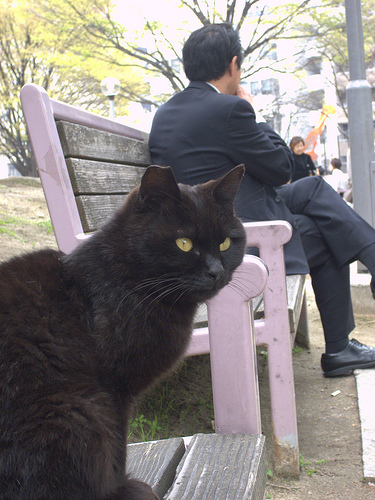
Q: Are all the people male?
A: No, they are both male and female.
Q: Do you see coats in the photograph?
A: Yes, there is a coat.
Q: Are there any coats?
A: Yes, there is a coat.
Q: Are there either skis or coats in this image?
A: Yes, there is a coat.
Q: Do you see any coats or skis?
A: Yes, there is a coat.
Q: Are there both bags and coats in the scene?
A: No, there is a coat but no bags.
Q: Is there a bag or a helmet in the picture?
A: No, there are no bags or helmets.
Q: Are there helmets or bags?
A: No, there are no bags or helmets.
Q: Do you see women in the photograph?
A: Yes, there is a woman.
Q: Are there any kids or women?
A: Yes, there is a woman.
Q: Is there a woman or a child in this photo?
A: Yes, there is a woman.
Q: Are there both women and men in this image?
A: Yes, there are both a woman and a man.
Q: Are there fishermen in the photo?
A: No, there are no fishermen.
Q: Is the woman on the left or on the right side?
A: The woman is on the right of the image.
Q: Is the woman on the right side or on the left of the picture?
A: The woman is on the right of the image.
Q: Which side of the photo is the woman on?
A: The woman is on the right of the image.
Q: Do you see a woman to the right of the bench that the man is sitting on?
A: Yes, there is a woman to the right of the bench.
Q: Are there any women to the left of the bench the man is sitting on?
A: No, the woman is to the right of the bench.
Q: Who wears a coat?
A: The woman wears a coat.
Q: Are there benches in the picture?
A: Yes, there is a bench.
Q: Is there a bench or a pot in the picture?
A: Yes, there is a bench.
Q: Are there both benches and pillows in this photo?
A: No, there is a bench but no pillows.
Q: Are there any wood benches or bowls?
A: Yes, there is a wood bench.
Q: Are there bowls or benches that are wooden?
A: Yes, the bench is wooden.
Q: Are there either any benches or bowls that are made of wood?
A: Yes, the bench is made of wood.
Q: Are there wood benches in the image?
A: Yes, there is a wood bench.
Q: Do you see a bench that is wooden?
A: Yes, there is a bench that is wooden.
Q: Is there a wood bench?
A: Yes, there is a bench that is made of wood.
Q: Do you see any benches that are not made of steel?
A: Yes, there is a bench that is made of wood.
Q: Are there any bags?
A: No, there are no bags.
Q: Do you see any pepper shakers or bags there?
A: No, there are no bags or pepper shakers.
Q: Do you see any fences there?
A: No, there are no fences.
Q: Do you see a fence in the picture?
A: No, there are no fences.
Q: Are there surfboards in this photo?
A: No, there are no surfboards.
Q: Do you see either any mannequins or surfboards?
A: No, there are no surfboards or mannequins.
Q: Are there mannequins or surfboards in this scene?
A: No, there are no surfboards or mannequins.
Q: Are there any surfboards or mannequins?
A: No, there are no surfboards or mannequins.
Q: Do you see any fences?
A: No, there are no fences.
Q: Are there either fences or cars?
A: No, there are no fences or cars.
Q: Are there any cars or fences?
A: No, there are no fences or cars.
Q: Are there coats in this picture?
A: Yes, there is a coat.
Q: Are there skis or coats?
A: Yes, there is a coat.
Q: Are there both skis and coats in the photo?
A: No, there is a coat but no skis.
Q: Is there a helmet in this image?
A: No, there are no helmets.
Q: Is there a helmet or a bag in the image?
A: No, there are no helmets or bags.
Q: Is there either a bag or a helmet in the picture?
A: No, there are no helmets or bags.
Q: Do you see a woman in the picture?
A: Yes, there is a woman.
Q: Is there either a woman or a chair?
A: Yes, there is a woman.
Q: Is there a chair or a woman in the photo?
A: Yes, there is a woman.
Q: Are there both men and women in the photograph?
A: Yes, there are both a woman and a man.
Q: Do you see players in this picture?
A: No, there are no players.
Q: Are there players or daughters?
A: No, there are no players or daughters.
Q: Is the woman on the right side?
A: Yes, the woman is on the right of the image.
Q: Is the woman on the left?
A: No, the woman is on the right of the image.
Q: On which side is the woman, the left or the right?
A: The woman is on the right of the image.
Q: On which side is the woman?
A: The woman is on the right of the image.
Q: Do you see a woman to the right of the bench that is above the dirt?
A: Yes, there is a woman to the right of the bench.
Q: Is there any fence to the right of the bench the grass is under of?
A: No, there is a woman to the right of the bench.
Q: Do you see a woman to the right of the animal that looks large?
A: Yes, there is a woman to the right of the cat.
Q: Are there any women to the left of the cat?
A: No, the woman is to the right of the cat.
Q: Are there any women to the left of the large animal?
A: No, the woman is to the right of the cat.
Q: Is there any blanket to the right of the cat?
A: No, there is a woman to the right of the cat.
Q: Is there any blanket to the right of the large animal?
A: No, there is a woman to the right of the cat.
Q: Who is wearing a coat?
A: The woman is wearing a coat.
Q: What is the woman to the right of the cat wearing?
A: The woman is wearing a coat.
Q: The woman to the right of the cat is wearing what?
A: The woman is wearing a coat.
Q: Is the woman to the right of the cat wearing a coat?
A: Yes, the woman is wearing a coat.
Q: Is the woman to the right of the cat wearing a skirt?
A: No, the woman is wearing a coat.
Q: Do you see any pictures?
A: No, there are no pictures.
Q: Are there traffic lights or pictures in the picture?
A: No, there are no pictures or traffic lights.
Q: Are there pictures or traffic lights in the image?
A: No, there are no pictures or traffic lights.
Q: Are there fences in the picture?
A: No, there are no fences.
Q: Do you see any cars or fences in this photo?
A: No, there are no fences or cars.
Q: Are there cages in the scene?
A: No, there are no cages.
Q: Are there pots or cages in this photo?
A: No, there are no cages or pots.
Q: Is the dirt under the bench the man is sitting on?
A: Yes, the dirt is under the bench.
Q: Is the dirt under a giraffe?
A: No, the dirt is under the bench.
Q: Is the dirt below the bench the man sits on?
A: Yes, the dirt is below the bench.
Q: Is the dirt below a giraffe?
A: No, the dirt is below the bench.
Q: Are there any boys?
A: No, there are no boys.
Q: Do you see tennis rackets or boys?
A: No, there are no boys or tennis rackets.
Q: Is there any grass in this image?
A: Yes, there is grass.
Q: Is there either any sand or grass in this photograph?
A: Yes, there is grass.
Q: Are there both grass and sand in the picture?
A: No, there is grass but no sand.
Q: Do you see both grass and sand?
A: No, there is grass but no sand.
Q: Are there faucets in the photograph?
A: No, there are no faucets.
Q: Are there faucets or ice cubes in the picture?
A: No, there are no faucets or ice cubes.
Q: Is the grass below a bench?
A: Yes, the grass is below a bench.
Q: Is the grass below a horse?
A: No, the grass is below a bench.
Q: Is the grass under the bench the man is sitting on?
A: Yes, the grass is under the bench.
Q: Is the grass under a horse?
A: No, the grass is under the bench.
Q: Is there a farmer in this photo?
A: No, there are no farmers.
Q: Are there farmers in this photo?
A: No, there are no farmers.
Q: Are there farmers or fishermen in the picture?
A: No, there are no farmers or fishermen.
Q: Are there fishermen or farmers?
A: No, there are no farmers or fishermen.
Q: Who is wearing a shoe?
A: The man is wearing a shoe.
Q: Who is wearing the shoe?
A: The man is wearing a shoe.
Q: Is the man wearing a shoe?
A: Yes, the man is wearing a shoe.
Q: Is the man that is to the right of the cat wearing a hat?
A: No, the man is wearing a shoe.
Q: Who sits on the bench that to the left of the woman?
A: The man sits on the bench.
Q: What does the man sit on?
A: The man sits on the bench.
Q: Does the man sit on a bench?
A: Yes, the man sits on a bench.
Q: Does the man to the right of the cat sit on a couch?
A: No, the man sits on a bench.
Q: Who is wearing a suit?
A: The man is wearing a suit.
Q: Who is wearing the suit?
A: The man is wearing a suit.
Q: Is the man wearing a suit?
A: Yes, the man is wearing a suit.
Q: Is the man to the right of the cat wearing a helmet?
A: No, the man is wearing a suit.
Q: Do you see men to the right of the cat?
A: Yes, there is a man to the right of the cat.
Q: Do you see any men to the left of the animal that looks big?
A: No, the man is to the right of the cat.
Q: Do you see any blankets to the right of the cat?
A: No, there is a man to the right of the cat.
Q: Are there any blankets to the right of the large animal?
A: No, there is a man to the right of the cat.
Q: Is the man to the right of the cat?
A: Yes, the man is to the right of the cat.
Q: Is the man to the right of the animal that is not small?
A: Yes, the man is to the right of the cat.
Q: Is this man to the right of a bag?
A: No, the man is to the right of the cat.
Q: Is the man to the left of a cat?
A: No, the man is to the right of a cat.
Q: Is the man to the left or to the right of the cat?
A: The man is to the right of the cat.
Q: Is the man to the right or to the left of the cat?
A: The man is to the right of the cat.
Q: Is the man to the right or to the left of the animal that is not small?
A: The man is to the right of the cat.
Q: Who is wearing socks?
A: The man is wearing socks.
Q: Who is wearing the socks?
A: The man is wearing socks.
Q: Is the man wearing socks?
A: Yes, the man is wearing socks.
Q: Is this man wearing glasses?
A: No, the man is wearing socks.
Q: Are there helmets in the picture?
A: No, there are no helmets.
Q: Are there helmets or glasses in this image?
A: No, there are no helmets or glasses.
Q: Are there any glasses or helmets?
A: No, there are no helmets or glasses.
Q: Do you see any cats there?
A: Yes, there is a cat.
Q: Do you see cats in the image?
A: Yes, there is a cat.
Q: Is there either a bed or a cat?
A: Yes, there is a cat.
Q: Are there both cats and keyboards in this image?
A: No, there is a cat but no keyboards.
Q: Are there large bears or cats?
A: Yes, there is a large cat.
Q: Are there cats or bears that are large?
A: Yes, the cat is large.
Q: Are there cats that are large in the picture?
A: Yes, there is a large cat.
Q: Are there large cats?
A: Yes, there is a large cat.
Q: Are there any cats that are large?
A: Yes, there is a cat that is large.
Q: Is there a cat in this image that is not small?
A: Yes, there is a large cat.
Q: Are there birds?
A: No, there are no birds.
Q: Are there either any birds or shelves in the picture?
A: No, there are no birds or shelves.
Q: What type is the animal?
A: The animal is a cat.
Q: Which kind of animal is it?
A: The animal is a cat.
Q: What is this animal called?
A: This is a cat.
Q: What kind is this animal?
A: This is a cat.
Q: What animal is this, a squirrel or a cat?
A: This is a cat.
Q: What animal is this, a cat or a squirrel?
A: This is a cat.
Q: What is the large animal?
A: The animal is a cat.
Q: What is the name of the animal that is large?
A: The animal is a cat.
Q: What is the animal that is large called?
A: The animal is a cat.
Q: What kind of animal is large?
A: The animal is a cat.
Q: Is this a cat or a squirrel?
A: This is a cat.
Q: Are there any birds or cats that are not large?
A: No, there is a cat but it is large.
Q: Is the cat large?
A: Yes, the cat is large.